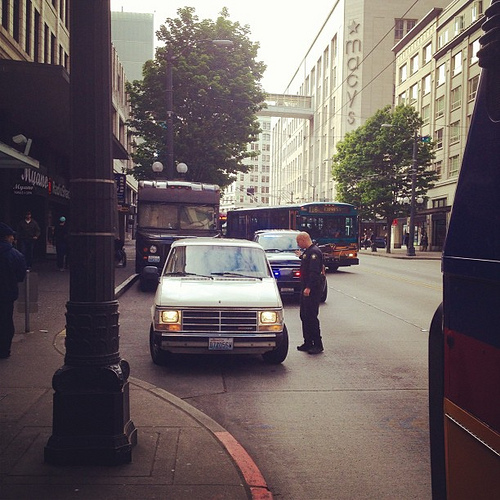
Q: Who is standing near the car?
A: Police officer.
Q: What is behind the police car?
A: Bus.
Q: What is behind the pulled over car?
A: UPS truck.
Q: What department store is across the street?
A: Macy's.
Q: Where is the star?
A: Above the word "Macy's".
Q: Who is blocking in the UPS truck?
A: The policeman.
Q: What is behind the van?
A: UPS truck.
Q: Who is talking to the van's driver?
A: A police officer.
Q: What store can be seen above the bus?
A: Macy's.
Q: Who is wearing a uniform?
A: Police officer.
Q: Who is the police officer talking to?
A: The van's driver.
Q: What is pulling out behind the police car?
A: A bus.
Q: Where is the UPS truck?
A: Behind the van.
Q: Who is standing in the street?
A: Police officer.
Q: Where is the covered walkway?
A: On the Macy's building.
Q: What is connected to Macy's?
A: A covered walkway.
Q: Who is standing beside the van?
A: Police officer.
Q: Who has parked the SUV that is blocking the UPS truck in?
A: Police man.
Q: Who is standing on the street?
A: Policeman.